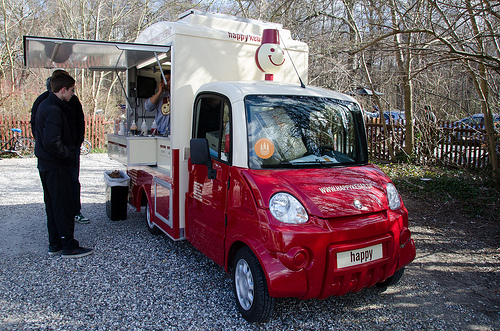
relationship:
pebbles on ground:
[4, 153, 468, 328] [1, 151, 499, 331]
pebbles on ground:
[4, 153, 468, 328] [418, 229, 453, 278]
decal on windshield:
[251, 134, 288, 165] [237, 87, 374, 169]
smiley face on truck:
[253, 26, 286, 74] [20, 8, 418, 323]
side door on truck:
[21, 33, 171, 85] [22, 19, 389, 300]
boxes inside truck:
[206, 97, 314, 168] [116, 9, 412, 314]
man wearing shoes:
[29, 72, 97, 261] [44, 242, 95, 259]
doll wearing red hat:
[257, 30, 286, 79] [258, 22, 283, 45]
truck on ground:
[141, 11, 441, 317] [1, 151, 499, 331]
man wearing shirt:
[42, 71, 94, 269] [32, 94, 75, 168]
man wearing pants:
[42, 71, 94, 269] [37, 156, 80, 249]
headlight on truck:
[267, 191, 311, 228] [116, 9, 412, 314]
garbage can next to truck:
[92, 158, 127, 213] [67, 29, 382, 325]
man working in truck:
[145, 77, 170, 133] [116, 9, 412, 314]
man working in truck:
[143, 77, 170, 133] [20, 8, 418, 323]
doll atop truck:
[257, 30, 286, 79] [186, 80, 415, 302]